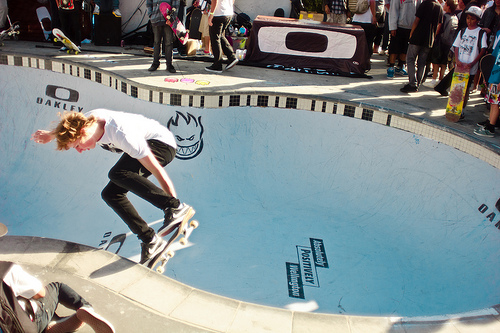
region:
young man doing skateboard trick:
[20, 89, 222, 289]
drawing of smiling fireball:
[155, 96, 211, 167]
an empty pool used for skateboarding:
[2, 37, 499, 328]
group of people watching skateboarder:
[65, 4, 498, 149]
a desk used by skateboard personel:
[242, 9, 386, 92]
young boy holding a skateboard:
[440, 4, 492, 131]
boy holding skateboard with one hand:
[37, 100, 207, 270]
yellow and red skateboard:
[441, 53, 476, 133]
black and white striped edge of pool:
[8, 45, 408, 145]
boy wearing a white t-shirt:
[55, 87, 191, 167]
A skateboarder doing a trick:
[24, 97, 210, 279]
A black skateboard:
[148, 216, 203, 280]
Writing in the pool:
[277, 227, 344, 316]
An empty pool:
[0, 57, 491, 319]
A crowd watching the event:
[173, 2, 498, 107]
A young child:
[446, 7, 490, 124]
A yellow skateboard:
[442, 55, 479, 125]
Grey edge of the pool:
[32, 238, 233, 323]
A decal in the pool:
[162, 107, 217, 171]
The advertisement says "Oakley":
[20, 81, 97, 115]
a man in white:
[52, 62, 204, 278]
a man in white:
[82, 112, 283, 328]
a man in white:
[110, 124, 207, 312]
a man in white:
[133, 169, 246, 331]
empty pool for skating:
[1, 50, 498, 327]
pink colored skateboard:
[157, 1, 195, 46]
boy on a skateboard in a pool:
[27, 101, 210, 278]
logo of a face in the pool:
[161, 107, 205, 164]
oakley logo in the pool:
[31, 78, 88, 118]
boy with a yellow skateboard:
[443, 1, 487, 125]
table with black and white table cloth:
[241, 10, 373, 81]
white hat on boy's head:
[462, 5, 483, 23]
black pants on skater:
[97, 139, 181, 247]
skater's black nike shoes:
[129, 197, 189, 260]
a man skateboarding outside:
[35, 71, 283, 307]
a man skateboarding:
[21, 82, 269, 330]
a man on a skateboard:
[32, 57, 272, 329]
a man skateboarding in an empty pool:
[30, 38, 314, 313]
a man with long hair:
[26, 53, 215, 305]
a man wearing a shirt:
[23, 78, 281, 314]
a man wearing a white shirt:
[32, 59, 294, 289]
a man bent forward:
[74, 80, 227, 277]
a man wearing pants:
[37, 82, 222, 280]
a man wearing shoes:
[43, 52, 263, 249]